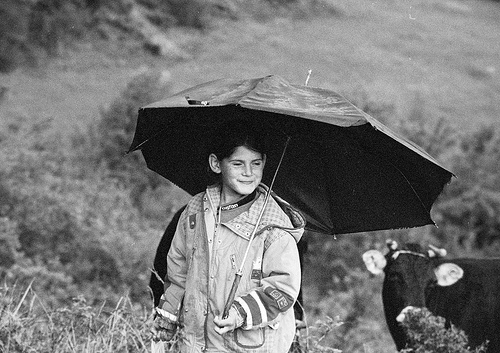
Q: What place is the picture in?
A: It is at the field.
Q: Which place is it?
A: It is a field.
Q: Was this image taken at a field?
A: Yes, it was taken in a field.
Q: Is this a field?
A: Yes, it is a field.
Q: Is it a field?
A: Yes, it is a field.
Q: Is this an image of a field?
A: Yes, it is showing a field.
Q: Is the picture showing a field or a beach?
A: It is showing a field.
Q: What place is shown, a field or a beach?
A: It is a field.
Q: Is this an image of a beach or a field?
A: It is showing a field.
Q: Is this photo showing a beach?
A: No, the picture is showing a field.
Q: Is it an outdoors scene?
A: Yes, it is outdoors.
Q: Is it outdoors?
A: Yes, it is outdoors.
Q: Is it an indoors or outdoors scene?
A: It is outdoors.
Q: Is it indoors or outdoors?
A: It is outdoors.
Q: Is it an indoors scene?
A: No, it is outdoors.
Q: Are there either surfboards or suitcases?
A: No, there are no suitcases or surfboards.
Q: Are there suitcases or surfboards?
A: No, there are no suitcases or surfboards.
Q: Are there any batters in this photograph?
A: No, there are no batters.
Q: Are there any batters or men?
A: No, there are no batters or men.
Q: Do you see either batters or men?
A: No, there are no batters or men.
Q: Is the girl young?
A: Yes, the girl is young.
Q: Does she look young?
A: Yes, the girl is young.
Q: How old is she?
A: The girl is young.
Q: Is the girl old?
A: No, the girl is young.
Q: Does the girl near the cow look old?
A: No, the girl is young.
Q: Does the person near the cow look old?
A: No, the girl is young.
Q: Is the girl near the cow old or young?
A: The girl is young.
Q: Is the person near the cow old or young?
A: The girl is young.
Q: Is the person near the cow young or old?
A: The girl is young.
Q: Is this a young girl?
A: Yes, this is a young girl.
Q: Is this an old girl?
A: No, this is a young girl.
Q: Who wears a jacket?
A: The girl wears a jacket.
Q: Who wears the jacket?
A: The girl wears a jacket.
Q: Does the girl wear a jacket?
A: Yes, the girl wears a jacket.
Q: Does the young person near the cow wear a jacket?
A: Yes, the girl wears a jacket.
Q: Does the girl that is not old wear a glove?
A: No, the girl wears a jacket.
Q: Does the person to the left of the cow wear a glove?
A: No, the girl wears a jacket.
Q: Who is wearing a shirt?
A: The girl is wearing a shirt.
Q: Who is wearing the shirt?
A: The girl is wearing a shirt.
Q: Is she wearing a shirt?
A: Yes, the girl is wearing a shirt.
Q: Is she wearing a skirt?
A: No, the girl is wearing a shirt.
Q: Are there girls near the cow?
A: Yes, there is a girl near the cow.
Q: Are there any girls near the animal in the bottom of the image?
A: Yes, there is a girl near the cow.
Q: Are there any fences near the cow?
A: No, there is a girl near the cow.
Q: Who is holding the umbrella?
A: The girl is holding the umbrella.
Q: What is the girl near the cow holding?
A: The girl is holding the umbrella.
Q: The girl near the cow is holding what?
A: The girl is holding the umbrella.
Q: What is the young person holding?
A: The girl is holding the umbrella.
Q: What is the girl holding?
A: The girl is holding the umbrella.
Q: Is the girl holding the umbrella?
A: Yes, the girl is holding the umbrella.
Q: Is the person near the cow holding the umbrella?
A: Yes, the girl is holding the umbrella.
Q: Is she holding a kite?
A: No, the girl is holding the umbrella.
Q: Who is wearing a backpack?
A: The girl is wearing a backpack.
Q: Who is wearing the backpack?
A: The girl is wearing a backpack.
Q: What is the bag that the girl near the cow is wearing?
A: The bag is a backpack.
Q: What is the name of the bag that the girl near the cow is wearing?
A: The bag is a backpack.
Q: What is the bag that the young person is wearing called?
A: The bag is a backpack.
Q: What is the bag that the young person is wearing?
A: The bag is a backpack.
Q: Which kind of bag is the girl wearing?
A: The girl is wearing a backpack.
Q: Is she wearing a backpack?
A: Yes, the girl is wearing a backpack.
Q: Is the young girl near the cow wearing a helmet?
A: No, the girl is wearing a backpack.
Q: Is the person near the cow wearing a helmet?
A: No, the girl is wearing a backpack.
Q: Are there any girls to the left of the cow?
A: Yes, there is a girl to the left of the cow.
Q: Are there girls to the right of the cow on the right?
A: No, the girl is to the left of the cow.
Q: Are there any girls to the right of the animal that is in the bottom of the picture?
A: No, the girl is to the left of the cow.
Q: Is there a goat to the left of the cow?
A: No, there is a girl to the left of the cow.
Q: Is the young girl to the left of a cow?
A: Yes, the girl is to the left of a cow.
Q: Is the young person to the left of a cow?
A: Yes, the girl is to the left of a cow.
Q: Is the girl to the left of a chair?
A: No, the girl is to the left of a cow.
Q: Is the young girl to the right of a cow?
A: No, the girl is to the left of a cow.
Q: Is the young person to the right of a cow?
A: No, the girl is to the left of a cow.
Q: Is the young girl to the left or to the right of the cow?
A: The girl is to the left of the cow.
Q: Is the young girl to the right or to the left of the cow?
A: The girl is to the left of the cow.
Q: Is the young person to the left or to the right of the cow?
A: The girl is to the left of the cow.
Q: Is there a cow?
A: Yes, there is a cow.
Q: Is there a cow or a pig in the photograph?
A: Yes, there is a cow.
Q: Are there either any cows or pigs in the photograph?
A: Yes, there is a cow.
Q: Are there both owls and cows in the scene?
A: No, there is a cow but no owls.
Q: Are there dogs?
A: No, there are no dogs.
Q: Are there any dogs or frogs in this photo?
A: No, there are no dogs or frogs.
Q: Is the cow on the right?
A: Yes, the cow is on the right of the image.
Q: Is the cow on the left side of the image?
A: No, the cow is on the right of the image.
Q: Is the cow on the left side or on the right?
A: The cow is on the right of the image.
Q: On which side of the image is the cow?
A: The cow is on the right of the image.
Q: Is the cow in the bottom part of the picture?
A: Yes, the cow is in the bottom of the image.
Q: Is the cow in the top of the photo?
A: No, the cow is in the bottom of the image.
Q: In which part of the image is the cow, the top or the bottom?
A: The cow is in the bottom of the image.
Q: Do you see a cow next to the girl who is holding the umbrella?
A: Yes, there is a cow next to the girl.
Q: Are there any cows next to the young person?
A: Yes, there is a cow next to the girl.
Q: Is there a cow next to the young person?
A: Yes, there is a cow next to the girl.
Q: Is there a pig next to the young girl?
A: No, there is a cow next to the girl.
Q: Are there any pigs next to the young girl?
A: No, there is a cow next to the girl.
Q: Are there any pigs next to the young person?
A: No, there is a cow next to the girl.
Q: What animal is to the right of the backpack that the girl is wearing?
A: The animal is a cow.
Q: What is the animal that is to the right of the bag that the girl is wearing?
A: The animal is a cow.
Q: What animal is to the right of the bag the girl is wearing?
A: The animal is a cow.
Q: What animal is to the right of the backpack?
A: The animal is a cow.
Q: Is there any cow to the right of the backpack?
A: Yes, there is a cow to the right of the backpack.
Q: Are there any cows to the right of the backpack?
A: Yes, there is a cow to the right of the backpack.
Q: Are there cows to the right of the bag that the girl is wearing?
A: Yes, there is a cow to the right of the backpack.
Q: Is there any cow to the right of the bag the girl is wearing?
A: Yes, there is a cow to the right of the backpack.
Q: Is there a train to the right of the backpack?
A: No, there is a cow to the right of the backpack.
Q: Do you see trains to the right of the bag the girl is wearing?
A: No, there is a cow to the right of the backpack.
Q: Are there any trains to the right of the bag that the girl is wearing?
A: No, there is a cow to the right of the backpack.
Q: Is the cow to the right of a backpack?
A: Yes, the cow is to the right of a backpack.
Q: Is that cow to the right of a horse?
A: No, the cow is to the right of a backpack.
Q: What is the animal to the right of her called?
A: The animal is a cow.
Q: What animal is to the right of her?
A: The animal is a cow.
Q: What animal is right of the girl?
A: The animal is a cow.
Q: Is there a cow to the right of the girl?
A: Yes, there is a cow to the right of the girl.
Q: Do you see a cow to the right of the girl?
A: Yes, there is a cow to the right of the girl.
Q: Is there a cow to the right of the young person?
A: Yes, there is a cow to the right of the girl.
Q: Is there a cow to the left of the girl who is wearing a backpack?
A: No, the cow is to the right of the girl.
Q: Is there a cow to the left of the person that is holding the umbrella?
A: No, the cow is to the right of the girl.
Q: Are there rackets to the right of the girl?
A: No, there is a cow to the right of the girl.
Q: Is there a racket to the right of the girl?
A: No, there is a cow to the right of the girl.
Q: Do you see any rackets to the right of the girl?
A: No, there is a cow to the right of the girl.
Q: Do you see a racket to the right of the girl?
A: No, there is a cow to the right of the girl.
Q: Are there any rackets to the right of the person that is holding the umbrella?
A: No, there is a cow to the right of the girl.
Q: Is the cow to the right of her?
A: Yes, the cow is to the right of a girl.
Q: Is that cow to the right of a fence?
A: No, the cow is to the right of a girl.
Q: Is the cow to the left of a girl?
A: No, the cow is to the right of a girl.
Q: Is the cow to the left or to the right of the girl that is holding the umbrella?
A: The cow is to the right of the girl.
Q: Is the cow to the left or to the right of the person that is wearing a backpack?
A: The cow is to the right of the girl.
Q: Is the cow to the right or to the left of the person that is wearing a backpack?
A: The cow is to the right of the girl.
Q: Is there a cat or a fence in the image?
A: No, there are no fences or cats.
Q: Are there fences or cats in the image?
A: No, there are no fences or cats.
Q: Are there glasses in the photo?
A: No, there are no glasses.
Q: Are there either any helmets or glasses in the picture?
A: No, there are no glasses or helmets.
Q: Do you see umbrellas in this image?
A: Yes, there is an umbrella.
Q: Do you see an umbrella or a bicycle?
A: Yes, there is an umbrella.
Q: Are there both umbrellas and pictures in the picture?
A: No, there is an umbrella but no pictures.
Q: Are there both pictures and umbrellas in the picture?
A: No, there is an umbrella but no pictures.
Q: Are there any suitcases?
A: No, there are no suitcases.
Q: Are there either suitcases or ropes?
A: No, there are no suitcases or ropes.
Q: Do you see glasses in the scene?
A: No, there are no glasses.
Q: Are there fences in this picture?
A: No, there are no fences.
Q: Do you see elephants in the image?
A: No, there are no elephants.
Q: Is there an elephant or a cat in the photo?
A: No, there are no elephants or cats.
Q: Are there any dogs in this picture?
A: No, there are no dogs.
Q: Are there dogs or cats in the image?
A: No, there are no dogs or cats.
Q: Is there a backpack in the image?
A: Yes, there is a backpack.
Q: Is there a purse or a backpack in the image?
A: Yes, there is a backpack.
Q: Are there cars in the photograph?
A: No, there are no cars.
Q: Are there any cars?
A: No, there are no cars.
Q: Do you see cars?
A: No, there are no cars.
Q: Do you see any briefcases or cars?
A: No, there are no cars or briefcases.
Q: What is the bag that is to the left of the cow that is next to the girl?
A: The bag is a backpack.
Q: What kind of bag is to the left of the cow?
A: The bag is a backpack.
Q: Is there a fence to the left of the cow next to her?
A: No, there is a backpack to the left of the cow.